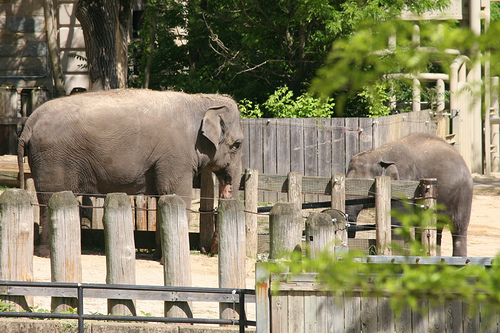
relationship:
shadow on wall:
[314, 294, 492, 330] [253, 260, 493, 330]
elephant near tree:
[14, 86, 248, 260] [72, 0, 209, 91]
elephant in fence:
[342, 129, 475, 253] [242, 109, 443, 208]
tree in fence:
[68, 3, 168, 234] [242, 109, 443, 208]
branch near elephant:
[302, 13, 497, 111] [14, 86, 248, 260]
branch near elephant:
[302, 13, 497, 111] [342, 129, 475, 253]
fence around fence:
[257, 253, 497, 330] [242, 109, 443, 208]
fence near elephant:
[0, 173, 453, 330] [14, 86, 248, 260]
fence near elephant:
[0, 173, 453, 330] [342, 129, 475, 253]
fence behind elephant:
[242, 105, 443, 203] [14, 86, 248, 260]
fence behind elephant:
[242, 105, 443, 203] [342, 129, 475, 253]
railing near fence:
[2, 279, 250, 330] [242, 109, 443, 208]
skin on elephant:
[89, 114, 137, 164] [14, 86, 248, 260]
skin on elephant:
[389, 147, 409, 169] [342, 129, 475, 253]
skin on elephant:
[192, 104, 205, 132] [14, 86, 248, 260]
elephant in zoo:
[14, 86, 248, 260] [2, 0, 495, 330]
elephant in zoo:
[342, 129, 475, 253] [2, 0, 495, 330]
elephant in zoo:
[342, 131, 473, 257] [2, 0, 495, 330]